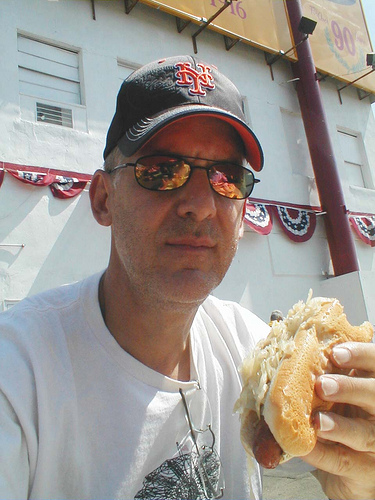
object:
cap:
[103, 55, 264, 172]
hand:
[298, 342, 374, 500]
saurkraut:
[231, 288, 331, 429]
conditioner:
[36, 102, 73, 128]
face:
[109, 115, 246, 302]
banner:
[243, 197, 375, 247]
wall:
[0, 0, 375, 299]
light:
[298, 16, 317, 35]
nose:
[177, 165, 217, 222]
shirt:
[0, 270, 274, 500]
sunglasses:
[108, 154, 261, 200]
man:
[0, 55, 375, 500]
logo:
[174, 62, 215, 97]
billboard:
[143, 0, 375, 94]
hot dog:
[253, 403, 287, 470]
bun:
[232, 288, 375, 465]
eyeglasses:
[178, 379, 224, 499]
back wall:
[259, 96, 306, 203]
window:
[17, 33, 88, 134]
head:
[87, 55, 244, 304]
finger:
[328, 341, 375, 372]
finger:
[315, 374, 375, 418]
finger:
[313, 411, 375, 454]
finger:
[300, 439, 375, 481]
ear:
[89, 169, 111, 225]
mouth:
[165, 237, 217, 252]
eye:
[211, 168, 243, 187]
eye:
[145, 161, 183, 181]